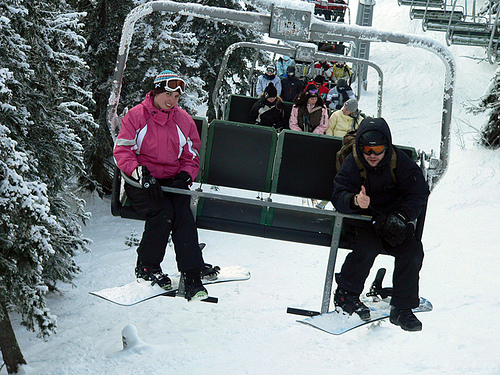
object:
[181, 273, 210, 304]
black/green shoes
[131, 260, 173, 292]
black/green shoes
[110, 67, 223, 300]
lady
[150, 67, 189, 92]
hat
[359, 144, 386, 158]
goggles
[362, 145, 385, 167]
face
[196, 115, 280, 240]
empty seat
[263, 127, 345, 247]
empty seat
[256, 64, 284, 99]
person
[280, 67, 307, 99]
person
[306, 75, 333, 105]
person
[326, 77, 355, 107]
person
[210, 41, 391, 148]
chairlift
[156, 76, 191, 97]
goggles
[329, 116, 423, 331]
people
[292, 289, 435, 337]
snowboards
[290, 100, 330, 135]
pink coat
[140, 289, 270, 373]
surface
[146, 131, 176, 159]
pink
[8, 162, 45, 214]
snow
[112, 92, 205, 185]
coat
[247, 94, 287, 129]
coat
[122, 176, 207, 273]
pants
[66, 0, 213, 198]
tree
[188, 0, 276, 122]
tree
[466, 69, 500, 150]
tree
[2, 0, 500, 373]
snow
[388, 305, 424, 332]
boot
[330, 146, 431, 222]
black jacket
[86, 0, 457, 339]
ski lift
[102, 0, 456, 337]
lift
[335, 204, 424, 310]
pants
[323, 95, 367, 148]
lady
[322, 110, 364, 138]
jacket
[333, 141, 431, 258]
seats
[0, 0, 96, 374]
tree